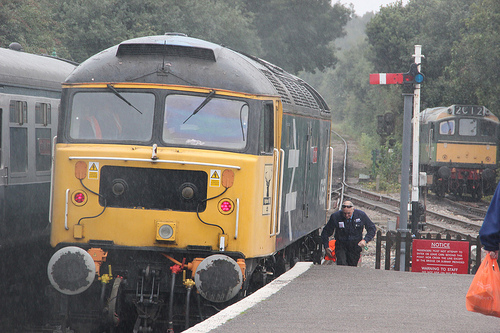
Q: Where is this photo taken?
A: A train station.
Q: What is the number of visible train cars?
A: There are three.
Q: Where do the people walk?
A: The platform.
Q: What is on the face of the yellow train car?
A: A windshield and head lights.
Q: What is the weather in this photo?
A: Gray and cloudy.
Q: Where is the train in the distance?
A: On the railroad tracks.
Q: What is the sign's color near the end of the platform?
A: The sign is red.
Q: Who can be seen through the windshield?
A: A person wearing an orange reflective safety vest.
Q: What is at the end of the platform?
A: A traffic signal.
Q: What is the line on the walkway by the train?
A: No cross line.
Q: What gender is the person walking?
A: Male.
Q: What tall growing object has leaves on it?
A: Tree.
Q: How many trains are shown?
A: 3.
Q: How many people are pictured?
A: One.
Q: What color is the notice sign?
A: Red.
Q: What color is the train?
A: Yellow.